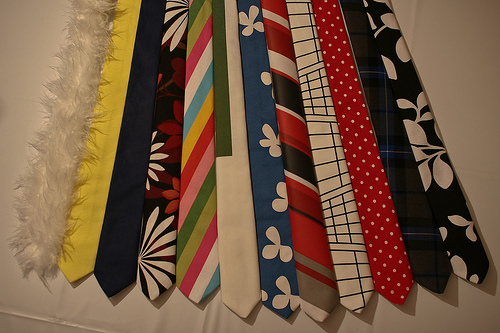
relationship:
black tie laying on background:
[92, 2, 165, 298] [0, 0, 499, 327]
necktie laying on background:
[173, 2, 218, 306] [0, 0, 499, 327]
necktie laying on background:
[284, 2, 373, 316] [0, 0, 499, 327]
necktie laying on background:
[237, 0, 301, 321] [0, 0, 499, 327]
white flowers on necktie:
[236, 4, 263, 35] [237, 0, 301, 321]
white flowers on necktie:
[261, 65, 275, 103] [237, 0, 301, 321]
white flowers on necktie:
[259, 122, 281, 162] [237, 0, 301, 321]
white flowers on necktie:
[259, 225, 293, 262] [237, 0, 301, 321]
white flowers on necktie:
[271, 180, 290, 215] [237, 0, 301, 321]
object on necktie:
[436, 213, 479, 285] [364, 0, 490, 282]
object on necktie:
[393, 84, 453, 194] [364, 0, 490, 282]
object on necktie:
[358, 3, 412, 84] [364, 0, 490, 282]